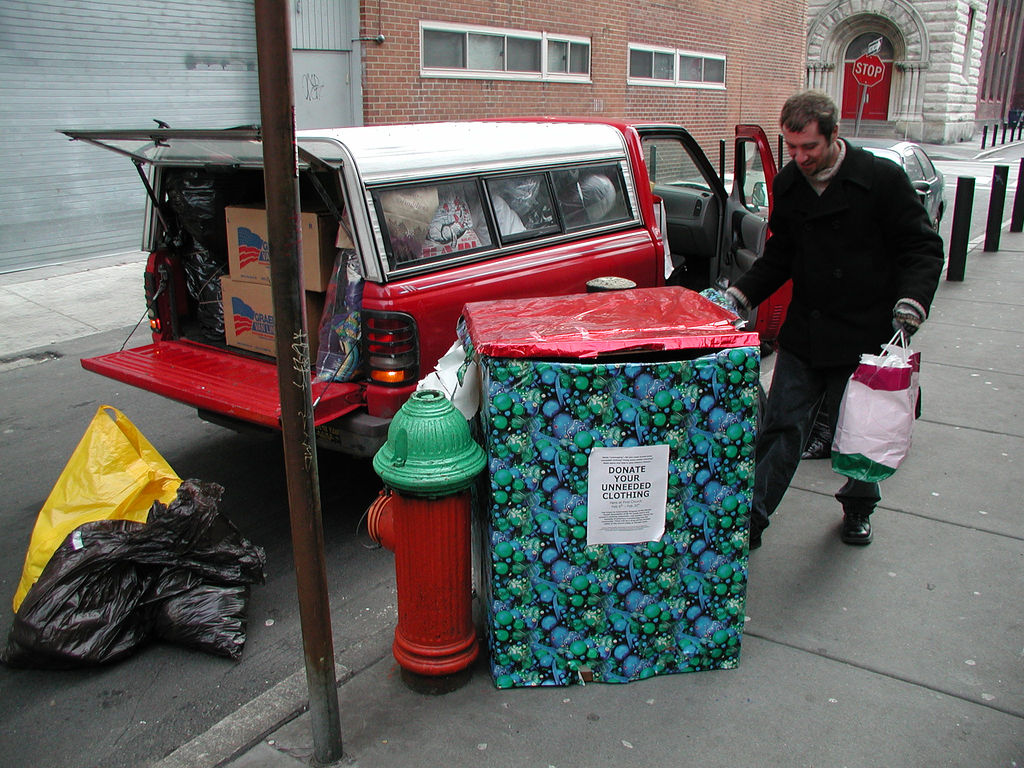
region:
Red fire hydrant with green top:
[356, 385, 509, 698]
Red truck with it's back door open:
[56, 105, 819, 469]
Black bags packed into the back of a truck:
[153, 164, 237, 346]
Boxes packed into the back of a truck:
[208, 177, 355, 378]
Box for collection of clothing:
[460, 293, 754, 695]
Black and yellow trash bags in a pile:
[21, 402, 272, 678]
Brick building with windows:
[357, 0, 819, 210]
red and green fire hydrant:
[361, 376, 491, 684]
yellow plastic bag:
[9, 401, 164, 588]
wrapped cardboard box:
[484, 298, 750, 690]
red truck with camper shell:
[110, 86, 804, 507]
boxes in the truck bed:
[189, 199, 325, 356]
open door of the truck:
[715, 118, 786, 357]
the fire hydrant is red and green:
[349, 387, 486, 688]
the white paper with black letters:
[588, 443, 668, 541]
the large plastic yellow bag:
[13, 402, 178, 611]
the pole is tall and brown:
[250, 0, 345, 762]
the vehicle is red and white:
[49, 115, 789, 463]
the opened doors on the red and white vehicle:
[48, 112, 789, 452]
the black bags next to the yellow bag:
[1, 399, 264, 665]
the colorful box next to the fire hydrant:
[354, 286, 760, 694]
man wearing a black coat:
[740, 66, 912, 599]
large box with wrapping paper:
[443, 256, 779, 690]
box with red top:
[446, 247, 776, 693]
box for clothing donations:
[453, 252, 739, 685]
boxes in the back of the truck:
[185, 176, 335, 369]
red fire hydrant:
[355, 372, 489, 696]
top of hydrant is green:
[342, 363, 495, 696]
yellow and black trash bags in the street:
[27, 391, 253, 704]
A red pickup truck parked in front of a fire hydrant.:
[57, 114, 807, 696]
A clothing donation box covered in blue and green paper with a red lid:
[457, 286, 756, 689]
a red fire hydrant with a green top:
[362, 386, 484, 688]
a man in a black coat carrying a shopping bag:
[710, 93, 946, 555]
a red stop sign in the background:
[844, 52, 887, 145]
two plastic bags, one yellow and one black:
[0, 401, 269, 671]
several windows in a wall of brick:
[358, 0, 805, 184]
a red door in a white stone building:
[803, 1, 990, 148]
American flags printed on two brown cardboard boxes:
[216, 197, 338, 365]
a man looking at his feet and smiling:
[718, 95, 949, 551]